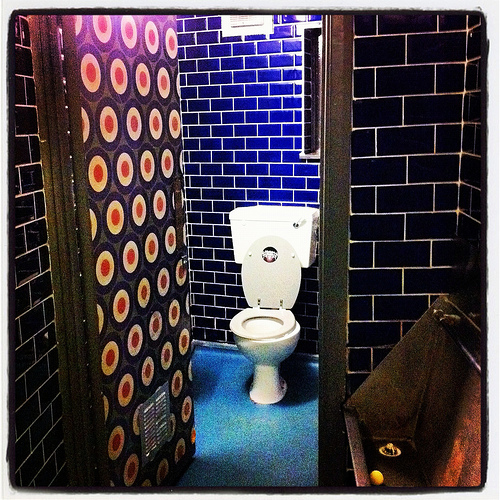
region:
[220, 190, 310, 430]
white ceramic toilet bowl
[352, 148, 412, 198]
blue tile on wall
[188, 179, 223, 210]
blue tile on wall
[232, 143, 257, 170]
blue tile on wall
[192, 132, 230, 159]
blue tile on wall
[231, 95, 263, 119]
blue tile on wall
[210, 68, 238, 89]
blue tile on wall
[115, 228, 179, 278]
circle design on door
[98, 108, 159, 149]
circle design on door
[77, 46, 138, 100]
circle design on door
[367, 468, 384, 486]
a yellow ball in a tub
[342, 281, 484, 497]
a metal tub attached to the wall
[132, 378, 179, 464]
a metal vent in the side of the wall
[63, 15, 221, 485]
red white and blue spotted wallpaper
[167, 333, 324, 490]
blue bathroom floor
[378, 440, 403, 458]
drain system in the tub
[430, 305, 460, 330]
faucet into the tub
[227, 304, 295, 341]
crooked toilet seat lid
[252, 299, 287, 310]
hinges on the toilet seat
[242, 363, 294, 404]
base of the white toilet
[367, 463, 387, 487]
A Yellow ball in a chair.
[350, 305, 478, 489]
The men's urinal in a public restroom.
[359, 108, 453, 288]
The wall has blue colored bricks.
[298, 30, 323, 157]
A small window in the restroom.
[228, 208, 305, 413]
a white toliet that is in the restroom.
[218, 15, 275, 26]
A white that is high on the wall.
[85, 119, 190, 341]
A door with red and black dots.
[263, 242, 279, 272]
A sticker on the bottom of the toilet seat.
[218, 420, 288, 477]
A blue colored floor.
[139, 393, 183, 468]
A silver vent on the floor.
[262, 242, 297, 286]
Sticker on toilet lid.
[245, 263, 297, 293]
Lid on toilet is white.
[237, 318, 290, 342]
Seat on toilet is white.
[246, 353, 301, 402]
White toilet in room.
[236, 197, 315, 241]
Tank on toilet is white.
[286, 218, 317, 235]
Silver flusher on toilet.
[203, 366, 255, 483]
Blue floor in bathroom.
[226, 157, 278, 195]
Blue tiles on wall in bathroom.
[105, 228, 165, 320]
Bullseye on wall in bathroom.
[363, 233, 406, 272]
Dark tiles on wall.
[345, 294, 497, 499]
this is a urinal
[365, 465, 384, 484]
a yellow ball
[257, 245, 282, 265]
a sticker on the toilet seat lid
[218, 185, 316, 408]
this is a toilet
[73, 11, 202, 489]
there is a circle pattern on the stall door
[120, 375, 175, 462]
a vent in the stall door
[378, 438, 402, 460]
this is a drain hole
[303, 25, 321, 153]
this is a window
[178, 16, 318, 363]
a tiled blue wall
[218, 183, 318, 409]
this is a white toilet